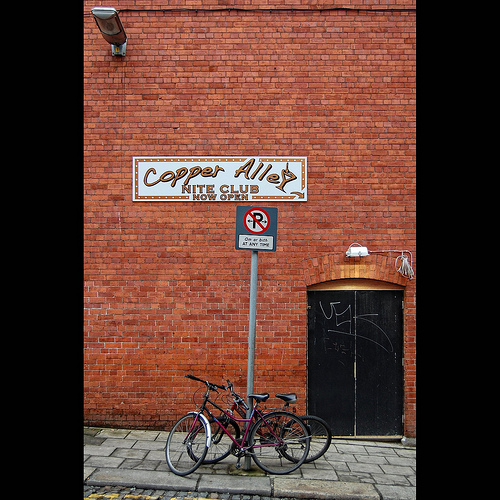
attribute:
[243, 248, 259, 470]
pole — metal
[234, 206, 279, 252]
sign — grey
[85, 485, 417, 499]
street — paved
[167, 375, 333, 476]
bikes — chained, numerous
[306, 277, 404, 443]
door — black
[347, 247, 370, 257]
light — on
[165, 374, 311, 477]
bike — red